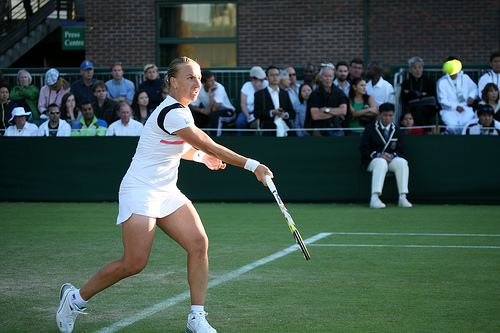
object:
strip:
[160, 138, 186, 145]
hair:
[169, 56, 184, 68]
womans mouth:
[193, 90, 199, 95]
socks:
[190, 303, 204, 316]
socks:
[73, 284, 89, 311]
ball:
[442, 59, 463, 76]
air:
[113, 29, 142, 49]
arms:
[338, 102, 347, 115]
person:
[5, 106, 37, 138]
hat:
[9, 106, 33, 124]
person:
[253, 66, 295, 135]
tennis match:
[57, 55, 315, 333]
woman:
[350, 76, 378, 134]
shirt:
[350, 100, 372, 131]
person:
[37, 68, 71, 114]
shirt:
[38, 79, 72, 114]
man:
[73, 60, 106, 102]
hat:
[76, 60, 94, 71]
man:
[103, 64, 134, 101]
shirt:
[101, 76, 141, 100]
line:
[115, 298, 157, 331]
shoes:
[183, 301, 217, 331]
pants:
[368, 157, 390, 194]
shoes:
[369, 196, 387, 208]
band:
[243, 158, 261, 174]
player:
[51, 55, 279, 333]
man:
[308, 63, 352, 138]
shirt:
[303, 84, 350, 132]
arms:
[310, 106, 323, 119]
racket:
[262, 174, 311, 261]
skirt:
[107, 171, 194, 227]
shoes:
[53, 278, 92, 331]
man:
[361, 101, 416, 210]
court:
[4, 191, 497, 328]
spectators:
[0, 53, 498, 136]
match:
[0, 47, 497, 332]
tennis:
[51, 44, 313, 333]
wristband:
[236, 157, 268, 178]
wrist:
[191, 146, 208, 166]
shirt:
[126, 93, 198, 193]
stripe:
[157, 98, 186, 135]